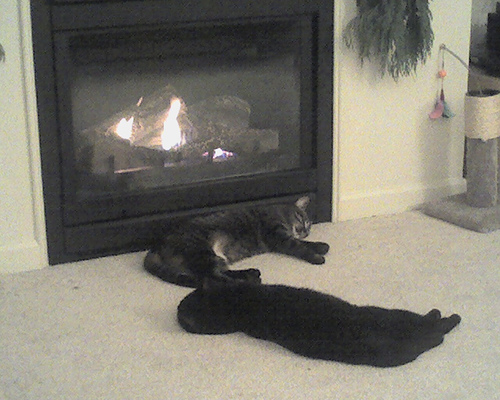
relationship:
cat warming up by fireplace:
[143, 189, 331, 288] [38, 11, 330, 251]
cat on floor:
[176, 272, 460, 367] [3, 273, 498, 398]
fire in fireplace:
[101, 72, 240, 175] [38, 11, 330, 251]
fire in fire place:
[101, 72, 240, 175] [27, 0, 335, 268]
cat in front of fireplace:
[176, 272, 460, 367] [25, 15, 350, 222]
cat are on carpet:
[143, 189, 331, 288] [0, 206, 497, 398]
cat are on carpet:
[176, 276, 460, 368] [0, 206, 497, 398]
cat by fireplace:
[178, 185, 335, 282] [53, 31, 325, 209]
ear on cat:
[295, 194, 310, 208] [143, 189, 331, 288]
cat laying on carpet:
[143, 189, 331, 288] [94, 282, 345, 388]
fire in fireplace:
[103, 72, 218, 161] [38, 11, 330, 251]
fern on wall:
[337, 0, 437, 82] [333, 0, 478, 222]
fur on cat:
[176, 277, 458, 367] [176, 272, 460, 367]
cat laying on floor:
[143, 189, 331, 288] [6, 228, 493, 396]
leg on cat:
[279, 241, 319, 261] [143, 189, 331, 288]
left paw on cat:
[307, 250, 326, 265] [143, 189, 331, 288]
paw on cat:
[442, 309, 467, 330] [179, 268, 469, 385]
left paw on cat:
[282, 217, 350, 262] [143, 189, 331, 288]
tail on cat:
[145, 251, 190, 284] [143, 189, 331, 288]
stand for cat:
[421, 79, 498, 239] [143, 189, 331, 288]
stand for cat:
[421, 79, 498, 239] [176, 272, 460, 367]